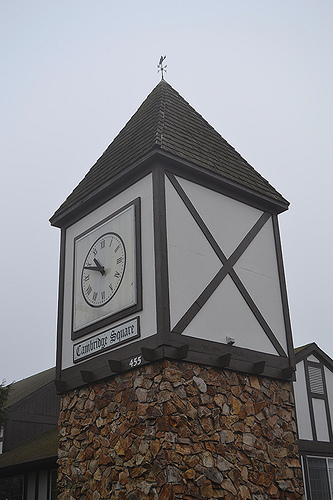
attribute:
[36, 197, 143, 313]
clock — white 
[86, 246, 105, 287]
hands — black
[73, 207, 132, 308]
clock — black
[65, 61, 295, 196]
tower — brown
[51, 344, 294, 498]
wall — stones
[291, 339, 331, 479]
building — brown, white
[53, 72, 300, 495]
tower — part stone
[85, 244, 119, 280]
22:49 — military time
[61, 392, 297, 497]
stone — brown, gray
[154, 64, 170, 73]
arrows — directional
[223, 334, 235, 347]
light — small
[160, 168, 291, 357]
x — big, wooden, large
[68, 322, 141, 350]
sign — Cambridge Square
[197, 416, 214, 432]
rock — large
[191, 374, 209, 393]
rock — large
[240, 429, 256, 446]
rock — large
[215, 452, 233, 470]
rock — large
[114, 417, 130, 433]
rock — large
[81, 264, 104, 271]
hand — black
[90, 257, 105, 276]
hand — black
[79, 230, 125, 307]
clock — black, white